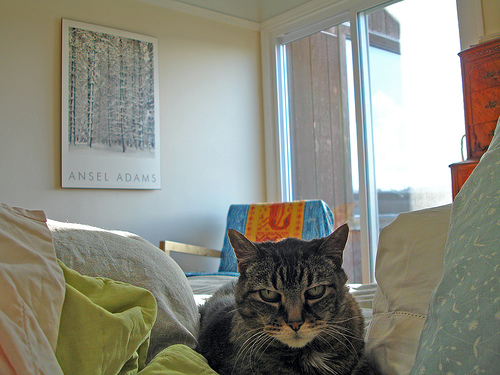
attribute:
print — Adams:
[52, 40, 160, 192]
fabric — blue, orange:
[217, 197, 334, 279]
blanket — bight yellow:
[54, 255, 221, 372]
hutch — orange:
[448, 40, 498, 202]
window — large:
[248, 24, 471, 238]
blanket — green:
[73, 257, 163, 361]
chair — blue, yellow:
[227, 214, 289, 231]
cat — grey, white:
[215, 237, 378, 364]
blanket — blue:
[456, 254, 494, 346]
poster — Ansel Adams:
[41, 19, 171, 196]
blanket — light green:
[61, 272, 171, 368]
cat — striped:
[217, 230, 375, 370]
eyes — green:
[250, 274, 338, 318]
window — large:
[244, 18, 463, 306]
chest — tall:
[447, 41, 497, 195]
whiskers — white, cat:
[235, 311, 349, 352]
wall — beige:
[162, 97, 223, 177]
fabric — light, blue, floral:
[452, 265, 483, 355]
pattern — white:
[455, 223, 498, 354]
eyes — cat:
[240, 278, 335, 302]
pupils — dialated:
[257, 290, 324, 295]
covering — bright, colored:
[219, 195, 341, 246]